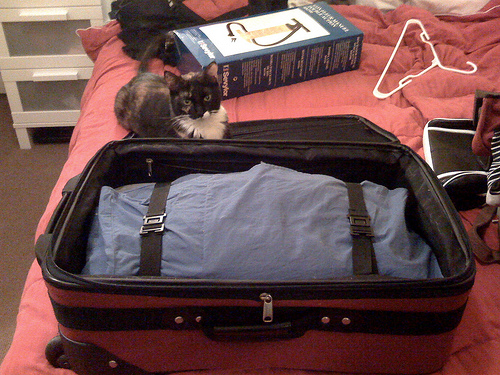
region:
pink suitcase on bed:
[50, 127, 378, 371]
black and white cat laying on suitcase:
[101, 60, 288, 157]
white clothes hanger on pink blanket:
[375, 10, 473, 114]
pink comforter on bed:
[88, 22, 493, 349]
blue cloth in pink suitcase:
[110, 164, 447, 374]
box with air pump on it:
[115, 11, 403, 102]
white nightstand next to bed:
[7, 1, 207, 193]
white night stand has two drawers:
[5, 4, 176, 171]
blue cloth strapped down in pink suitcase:
[51, 105, 465, 362]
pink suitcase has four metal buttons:
[112, 148, 466, 343]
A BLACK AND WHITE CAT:
[94, 34, 256, 151]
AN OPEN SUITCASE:
[30, 98, 481, 363]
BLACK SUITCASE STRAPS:
[100, 155, 405, 280]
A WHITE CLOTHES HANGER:
[360, 3, 490, 110]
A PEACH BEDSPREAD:
[15, 10, 495, 365]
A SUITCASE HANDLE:
[195, 312, 325, 345]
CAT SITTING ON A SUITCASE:
[98, 10, 311, 165]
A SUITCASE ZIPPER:
[152, 272, 387, 332]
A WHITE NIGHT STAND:
[6, 0, 122, 153]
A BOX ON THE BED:
[171, 3, 374, 102]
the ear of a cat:
[159, 65, 187, 93]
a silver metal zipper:
[256, 290, 276, 327]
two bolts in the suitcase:
[314, 311, 359, 328]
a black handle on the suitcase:
[194, 303, 317, 347]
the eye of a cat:
[200, 87, 217, 104]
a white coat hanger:
[371, 16, 481, 102]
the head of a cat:
[153, 51, 240, 128]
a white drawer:
[0, 63, 108, 130]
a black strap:
[343, 176, 375, 290]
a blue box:
[136, 1, 373, 108]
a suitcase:
[52, 113, 476, 373]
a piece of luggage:
[37, 122, 475, 372]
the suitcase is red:
[42, 109, 469, 374]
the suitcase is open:
[41, 111, 467, 368]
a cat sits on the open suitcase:
[63, 57, 409, 180]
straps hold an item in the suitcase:
[140, 160, 397, 276]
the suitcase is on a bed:
[25, 31, 481, 373]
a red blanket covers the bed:
[13, 12, 498, 372]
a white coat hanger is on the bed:
[371, 14, 482, 104]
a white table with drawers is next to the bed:
[0, 5, 116, 152]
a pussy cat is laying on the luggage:
[108, 29, 228, 136]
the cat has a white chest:
[164, 65, 227, 139]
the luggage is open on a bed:
[16, 87, 498, 367]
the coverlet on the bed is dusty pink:
[27, 15, 491, 358]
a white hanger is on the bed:
[369, 14, 478, 102]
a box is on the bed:
[168, 7, 361, 99]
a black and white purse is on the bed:
[422, 110, 499, 267]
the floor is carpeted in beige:
[5, 89, 73, 358]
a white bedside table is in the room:
[3, 5, 113, 148]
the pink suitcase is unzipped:
[35, 113, 475, 353]